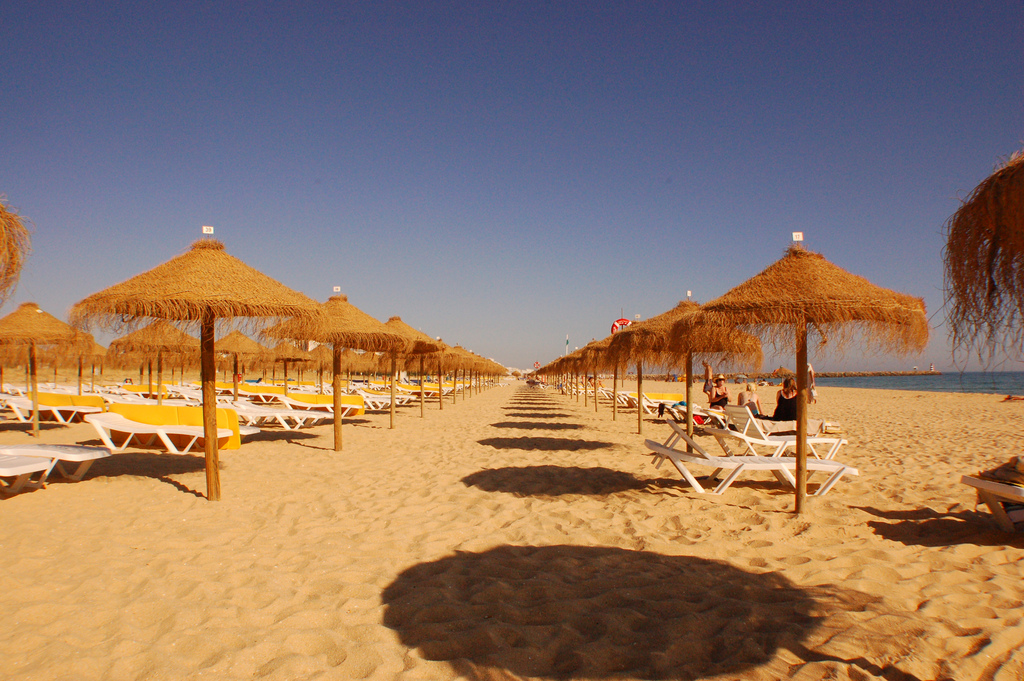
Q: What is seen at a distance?
A: Ocean.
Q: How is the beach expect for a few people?
A: Empty.